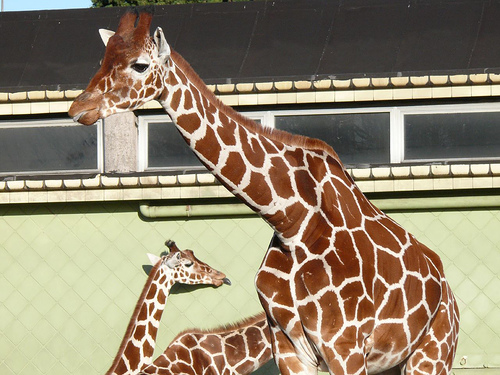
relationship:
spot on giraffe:
[220, 149, 247, 188] [61, 9, 461, 373]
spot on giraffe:
[243, 169, 272, 209] [61, 9, 461, 373]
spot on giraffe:
[371, 246, 406, 286] [61, 9, 461, 373]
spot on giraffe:
[400, 272, 425, 312] [61, 9, 461, 373]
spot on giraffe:
[191, 122, 221, 168] [61, 9, 461, 373]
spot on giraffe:
[133, 321, 148, 340] [103, 238, 228, 373]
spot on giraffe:
[421, 276, 443, 317] [61, 9, 461, 373]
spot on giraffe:
[329, 282, 367, 320] [61, 9, 461, 373]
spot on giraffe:
[357, 219, 403, 255] [61, 9, 461, 373]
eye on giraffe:
[130, 59, 151, 79] [61, 9, 461, 373]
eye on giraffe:
[180, 259, 194, 272] [103, 238, 228, 373]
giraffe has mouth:
[61, 9, 461, 373] [65, 102, 101, 128]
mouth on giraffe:
[68, 107, 99, 125] [61, 9, 461, 373]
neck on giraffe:
[175, 70, 292, 230] [61, 9, 461, 373]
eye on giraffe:
[178, 251, 205, 277] [74, 194, 277, 372]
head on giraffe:
[24, 12, 209, 137] [61, 9, 461, 373]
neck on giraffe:
[117, 286, 187, 371] [104, 238, 231, 375]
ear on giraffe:
[144, 18, 186, 75] [61, 9, 461, 373]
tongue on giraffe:
[58, 102, 101, 132] [61, 9, 461, 373]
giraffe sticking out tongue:
[95, 236, 241, 373] [218, 277, 235, 286]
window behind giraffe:
[405, 111, 500, 165] [61, 9, 461, 373]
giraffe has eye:
[61, 9, 461, 373] [125, 58, 152, 78]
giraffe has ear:
[61, 9, 461, 373] [146, 21, 173, 73]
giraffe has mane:
[61, 9, 461, 373] [170, 49, 340, 166]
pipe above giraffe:
[136, 200, 259, 219] [61, 9, 461, 373]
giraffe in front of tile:
[95, 236, 241, 373] [6, 216, 103, 309]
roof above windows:
[0, 1, 500, 100] [0, 103, 481, 192]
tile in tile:
[6, 216, 103, 309] [6, 216, 103, 309]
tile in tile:
[66, 216, 103, 245] [6, 216, 103, 309]